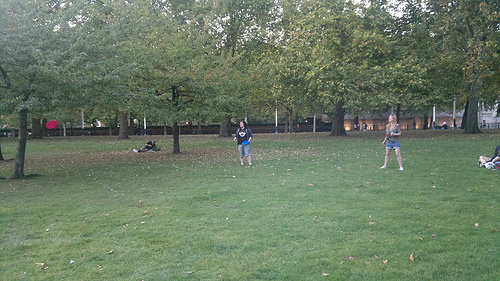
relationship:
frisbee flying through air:
[39, 110, 64, 135] [204, 109, 292, 141]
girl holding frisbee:
[233, 119, 253, 166] [240, 139, 250, 147]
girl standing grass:
[233, 119, 253, 166] [1, 127, 498, 279]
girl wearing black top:
[233, 119, 253, 166] [233, 126, 252, 144]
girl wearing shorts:
[379, 114, 404, 171] [380, 128, 410, 150]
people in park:
[234, 114, 404, 171] [3, 1, 498, 279]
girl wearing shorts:
[233, 119, 253, 166] [239, 137, 402, 154]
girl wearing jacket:
[233, 119, 253, 166] [219, 126, 254, 144]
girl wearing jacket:
[233, 119, 253, 166] [235, 126, 254, 145]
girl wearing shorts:
[211, 114, 299, 175] [209, 137, 260, 151]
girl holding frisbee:
[233, 119, 253, 166] [235, 135, 259, 149]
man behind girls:
[145, 140, 156, 153] [130, 135, 155, 154]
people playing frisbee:
[225, 114, 408, 176] [41, 118, 61, 130]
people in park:
[225, 114, 408, 176] [3, 1, 498, 279]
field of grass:
[5, 127, 484, 275] [1, 127, 498, 279]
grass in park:
[1, 127, 498, 279] [3, 1, 498, 279]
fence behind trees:
[7, 121, 427, 133] [253, 25, 339, 87]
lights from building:
[343, 120, 353, 133] [334, 106, 421, 133]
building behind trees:
[334, 106, 421, 133] [4, 3, 484, 180]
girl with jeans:
[375, 114, 417, 172] [385, 138, 400, 149]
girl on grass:
[375, 114, 417, 172] [1, 127, 498, 279]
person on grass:
[474, 142, 499, 169] [1, 127, 498, 279]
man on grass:
[145, 140, 156, 153] [1, 127, 498, 279]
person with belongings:
[474, 142, 499, 169] [146, 145, 163, 152]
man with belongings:
[145, 140, 156, 153] [485, 158, 497, 171]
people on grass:
[131, 137, 164, 154] [1, 127, 498, 279]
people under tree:
[132, 140, 157, 152] [73, 14, 191, 156]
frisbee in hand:
[239, 138, 251, 147] [245, 137, 250, 141]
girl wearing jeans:
[379, 114, 404, 171] [384, 139, 400, 148]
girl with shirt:
[379, 114, 404, 171] [383, 128, 401, 139]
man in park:
[132, 139, 159, 154] [3, 1, 498, 279]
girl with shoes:
[379, 114, 404, 171] [375, 161, 407, 172]